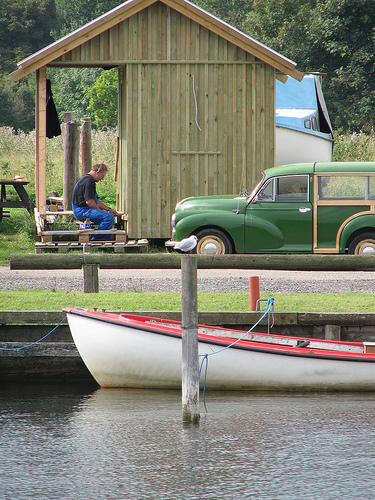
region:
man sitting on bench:
[71, 160, 128, 232]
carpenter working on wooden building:
[69, 2, 171, 230]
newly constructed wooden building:
[9, 1, 305, 239]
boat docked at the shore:
[58, 275, 369, 397]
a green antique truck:
[167, 160, 370, 255]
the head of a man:
[88, 161, 109, 180]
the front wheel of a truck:
[189, 225, 237, 256]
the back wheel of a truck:
[347, 225, 373, 253]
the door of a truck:
[243, 169, 313, 253]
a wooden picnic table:
[0, 172, 36, 218]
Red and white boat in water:
[61, 305, 372, 387]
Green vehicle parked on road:
[165, 162, 373, 254]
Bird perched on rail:
[167, 234, 199, 253]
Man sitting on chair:
[70, 159, 110, 244]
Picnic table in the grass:
[1, 170, 31, 215]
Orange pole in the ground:
[247, 274, 260, 310]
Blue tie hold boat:
[185, 297, 272, 410]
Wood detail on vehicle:
[310, 168, 374, 254]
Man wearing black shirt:
[71, 174, 99, 208]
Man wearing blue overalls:
[69, 176, 114, 230]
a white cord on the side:
[188, 74, 204, 132]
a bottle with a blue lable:
[80, 220, 92, 229]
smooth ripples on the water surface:
[299, 468, 372, 496]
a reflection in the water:
[82, 393, 362, 417]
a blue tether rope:
[222, 311, 270, 352]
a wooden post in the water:
[176, 255, 198, 426]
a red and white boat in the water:
[66, 300, 370, 389]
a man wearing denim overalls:
[74, 153, 118, 225]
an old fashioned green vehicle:
[155, 160, 373, 251]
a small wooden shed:
[15, 2, 273, 230]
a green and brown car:
[169, 162, 374, 257]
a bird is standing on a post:
[173, 233, 197, 254]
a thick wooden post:
[180, 257, 199, 428]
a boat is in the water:
[62, 306, 374, 394]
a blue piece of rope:
[198, 299, 273, 356]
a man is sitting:
[71, 162, 117, 239]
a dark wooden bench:
[1, 178, 32, 224]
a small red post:
[247, 274, 260, 310]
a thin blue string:
[0, 312, 68, 351]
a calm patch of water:
[0, 375, 373, 498]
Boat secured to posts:
[62, 300, 369, 390]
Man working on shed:
[71, 158, 119, 225]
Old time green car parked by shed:
[163, 154, 371, 255]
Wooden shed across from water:
[7, 0, 302, 248]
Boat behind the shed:
[274, 67, 334, 161]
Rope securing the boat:
[199, 294, 274, 355]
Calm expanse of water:
[1, 386, 371, 496]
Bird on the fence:
[163, 232, 198, 257]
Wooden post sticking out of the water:
[180, 251, 198, 424]